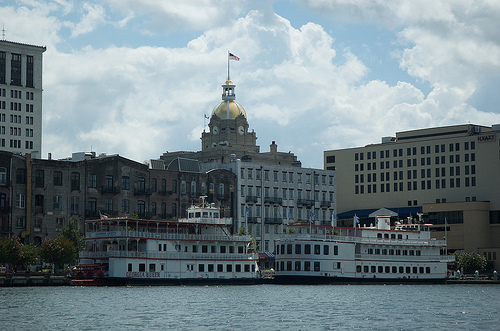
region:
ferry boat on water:
[266, 222, 465, 284]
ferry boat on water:
[100, 203, 263, 283]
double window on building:
[458, 175, 478, 187]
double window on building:
[431, 179, 446, 190]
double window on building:
[418, 179, 434, 190]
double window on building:
[403, 182, 416, 191]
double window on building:
[393, 181, 404, 192]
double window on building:
[377, 180, 389, 194]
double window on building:
[366, 183, 378, 193]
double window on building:
[351, 184, 366, 195]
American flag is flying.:
[218, 44, 250, 81]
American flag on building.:
[159, 42, 309, 169]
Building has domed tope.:
[143, 19, 308, 176]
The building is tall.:
[0, 32, 56, 282]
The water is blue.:
[2, 285, 498, 326]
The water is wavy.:
[0, 286, 495, 328]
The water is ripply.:
[1, 284, 499, 329]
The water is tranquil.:
[0, 285, 499, 329]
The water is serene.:
[1, 283, 498, 329]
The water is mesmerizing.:
[0, 285, 499, 330]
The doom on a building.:
[206, 95, 252, 125]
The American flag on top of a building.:
[215, 40, 246, 82]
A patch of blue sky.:
[340, 25, 365, 35]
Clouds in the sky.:
[97, 10, 432, 46]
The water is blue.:
[72, 295, 393, 320]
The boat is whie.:
[71, 190, 276, 286]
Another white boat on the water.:
[265, 187, 455, 287]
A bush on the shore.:
[455, 241, 491, 271]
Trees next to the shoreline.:
[2, 217, 82, 272]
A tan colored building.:
[319, 111, 499, 211]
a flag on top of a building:
[219, 48, 244, 73]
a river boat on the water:
[86, 180, 262, 291]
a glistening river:
[3, 282, 497, 329]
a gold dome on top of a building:
[213, 100, 246, 123]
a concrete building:
[214, 151, 344, 238]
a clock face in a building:
[237, 125, 247, 138]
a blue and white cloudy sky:
[0, 1, 497, 152]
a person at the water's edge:
[470, 267, 483, 279]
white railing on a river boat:
[274, 230, 318, 243]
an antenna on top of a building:
[0, 17, 15, 44]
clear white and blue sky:
[63, 15, 206, 104]